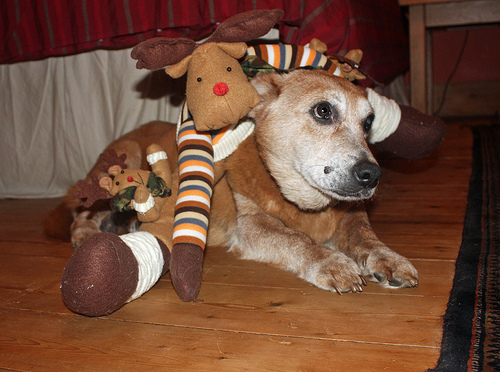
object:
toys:
[52, 8, 447, 317]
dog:
[43, 68, 423, 296]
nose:
[350, 158, 385, 184]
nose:
[212, 82, 229, 99]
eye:
[309, 99, 340, 121]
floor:
[394, 166, 452, 236]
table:
[392, 0, 499, 117]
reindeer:
[130, 4, 387, 302]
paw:
[360, 253, 418, 288]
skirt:
[210, 117, 258, 163]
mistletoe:
[100, 8, 148, 42]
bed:
[0, 0, 413, 201]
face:
[256, 68, 383, 202]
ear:
[245, 68, 287, 121]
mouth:
[304, 151, 384, 201]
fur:
[212, 310, 305, 358]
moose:
[95, 142, 172, 225]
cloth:
[3, 66, 151, 171]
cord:
[428, 30, 471, 121]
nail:
[353, 276, 370, 287]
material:
[308, 7, 378, 40]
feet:
[355, 229, 422, 272]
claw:
[303, 248, 369, 296]